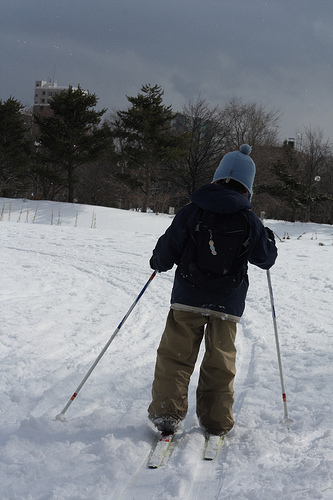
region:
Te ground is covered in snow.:
[29, 233, 94, 324]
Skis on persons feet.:
[113, 391, 255, 474]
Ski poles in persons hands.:
[112, 235, 312, 360]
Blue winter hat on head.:
[178, 134, 283, 224]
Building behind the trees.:
[6, 56, 124, 250]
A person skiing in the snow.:
[122, 134, 287, 467]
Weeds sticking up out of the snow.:
[5, 199, 98, 245]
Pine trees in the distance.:
[7, 86, 164, 213]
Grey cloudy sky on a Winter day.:
[97, 19, 280, 97]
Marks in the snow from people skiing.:
[29, 241, 159, 322]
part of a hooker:
[277, 391, 296, 428]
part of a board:
[213, 434, 224, 448]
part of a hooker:
[273, 391, 313, 436]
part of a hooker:
[273, 354, 323, 404]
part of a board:
[146, 442, 169, 480]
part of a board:
[203, 437, 227, 477]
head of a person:
[189, 135, 285, 217]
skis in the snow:
[119, 373, 262, 490]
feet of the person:
[127, 376, 264, 454]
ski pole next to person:
[55, 283, 156, 389]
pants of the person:
[123, 307, 259, 421]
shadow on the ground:
[68, 418, 116, 452]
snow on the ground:
[10, 314, 87, 372]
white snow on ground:
[1, 305, 79, 350]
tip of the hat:
[233, 137, 258, 159]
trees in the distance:
[34, 110, 170, 174]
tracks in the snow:
[120, 446, 236, 498]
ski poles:
[261, 256, 300, 434]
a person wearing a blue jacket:
[156, 140, 272, 439]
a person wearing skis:
[159, 146, 268, 459]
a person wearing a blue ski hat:
[152, 146, 279, 445]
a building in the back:
[33, 80, 66, 114]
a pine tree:
[114, 88, 179, 209]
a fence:
[1, 201, 99, 229]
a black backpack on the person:
[196, 208, 246, 284]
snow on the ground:
[34, 236, 103, 306]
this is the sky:
[180, 11, 266, 51]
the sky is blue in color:
[220, 0, 284, 50]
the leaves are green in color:
[136, 98, 153, 125]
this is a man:
[148, 135, 218, 490]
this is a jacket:
[195, 215, 242, 296]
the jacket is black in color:
[182, 229, 229, 274]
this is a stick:
[258, 269, 304, 376]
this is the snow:
[238, 421, 269, 454]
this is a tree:
[114, 89, 171, 185]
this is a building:
[31, 78, 53, 106]